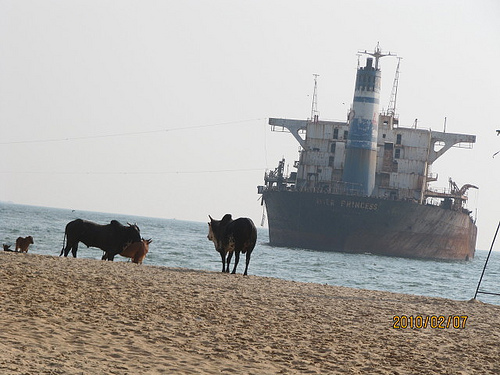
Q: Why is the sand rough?
A: Trampled with footprints.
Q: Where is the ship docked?
A: Near beach.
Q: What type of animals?
A: Bovines.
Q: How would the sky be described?
A: Gloomy.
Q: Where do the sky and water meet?
A: Horizon.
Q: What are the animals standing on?
A: Sand.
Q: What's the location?
A: Beach.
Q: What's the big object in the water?
A: Ship.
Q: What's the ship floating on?
A: Water.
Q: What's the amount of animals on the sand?
A: Four.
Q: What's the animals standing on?
A: Sand.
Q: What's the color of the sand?
A: Beige.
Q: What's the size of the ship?
A: Large.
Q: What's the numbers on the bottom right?
A: Date.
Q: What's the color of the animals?
A: Brown.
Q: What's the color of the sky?
A: Gray.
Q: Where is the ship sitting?
A: In ocean.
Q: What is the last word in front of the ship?
A: Princess.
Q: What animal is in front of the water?
A: Cow and dog.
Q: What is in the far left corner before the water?
A: A dog.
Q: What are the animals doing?
A: Standing.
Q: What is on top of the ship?
A: A tower.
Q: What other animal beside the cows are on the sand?
A: Dog.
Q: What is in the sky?
A: Clouds.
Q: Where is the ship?
A: In the water.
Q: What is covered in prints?
A: Sand on beach.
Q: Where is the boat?
A: In the ocean.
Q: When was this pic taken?
A: During the daytime.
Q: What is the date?
A: 02/07/2010.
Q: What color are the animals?
A: Dark brown.